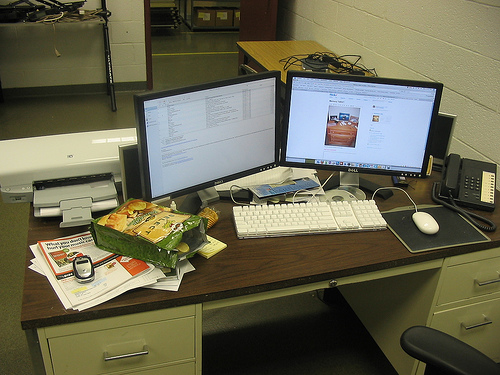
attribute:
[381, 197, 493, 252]
mouse pad — black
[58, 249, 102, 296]
flip phone — silver 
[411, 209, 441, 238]
mouse — white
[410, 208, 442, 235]
mouse — white 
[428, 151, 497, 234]
phone — black 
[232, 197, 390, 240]
keyboard — white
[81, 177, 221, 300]
bag — green 